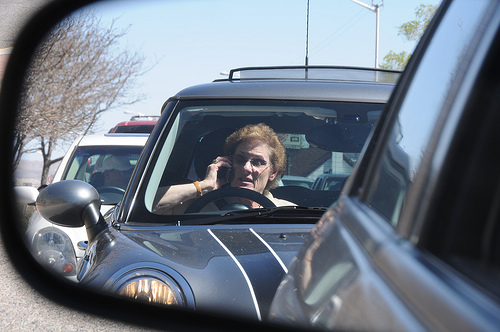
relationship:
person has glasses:
[168, 120, 320, 220] [231, 150, 266, 170]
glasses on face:
[231, 150, 266, 170] [225, 147, 279, 191]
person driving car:
[175, 129, 324, 220] [74, 62, 428, 329]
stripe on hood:
[207, 226, 298, 325] [88, 201, 334, 313]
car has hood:
[83, 65, 458, 326] [88, 201, 334, 313]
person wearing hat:
[94, 149, 138, 200] [98, 152, 138, 175]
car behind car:
[21, 128, 152, 283] [38, 63, 406, 318]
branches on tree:
[40, 25, 151, 158] [28, 27, 145, 184]